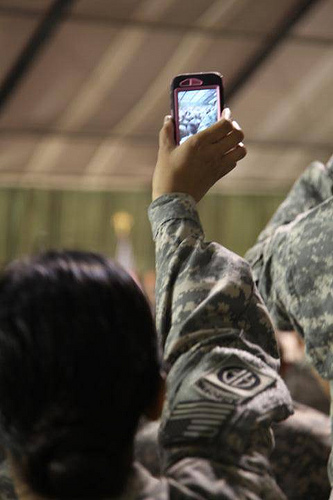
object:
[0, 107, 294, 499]
woman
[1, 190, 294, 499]
army uniform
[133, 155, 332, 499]
person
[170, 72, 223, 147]
cellphone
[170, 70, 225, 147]
case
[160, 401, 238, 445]
american flag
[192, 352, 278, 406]
patch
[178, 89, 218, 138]
screen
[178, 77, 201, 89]
speaker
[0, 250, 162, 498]
hair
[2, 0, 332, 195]
ceiling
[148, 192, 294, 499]
sleeve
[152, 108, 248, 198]
hand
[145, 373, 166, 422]
ear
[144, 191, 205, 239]
cuff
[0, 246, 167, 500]
head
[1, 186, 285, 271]
wall